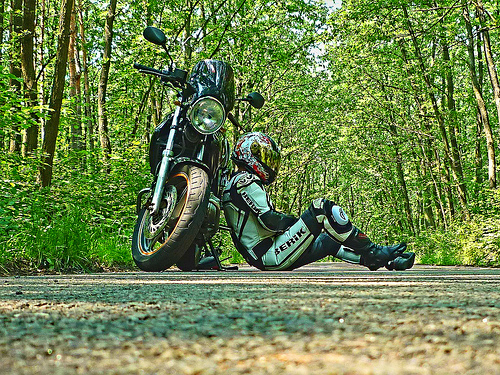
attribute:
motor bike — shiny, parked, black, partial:
[127, 26, 267, 269]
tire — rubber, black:
[127, 158, 209, 274]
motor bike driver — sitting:
[225, 131, 416, 270]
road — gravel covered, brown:
[3, 257, 498, 374]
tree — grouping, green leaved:
[41, 3, 72, 192]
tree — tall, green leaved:
[99, 3, 120, 178]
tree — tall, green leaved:
[357, 6, 422, 234]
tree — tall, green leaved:
[396, 3, 469, 220]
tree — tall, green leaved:
[271, 81, 315, 214]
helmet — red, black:
[234, 128, 280, 180]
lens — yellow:
[248, 140, 283, 173]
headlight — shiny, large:
[191, 94, 229, 136]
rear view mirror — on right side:
[141, 21, 185, 73]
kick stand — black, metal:
[205, 233, 237, 274]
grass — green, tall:
[7, 214, 146, 280]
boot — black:
[359, 238, 405, 269]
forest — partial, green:
[3, 1, 499, 270]